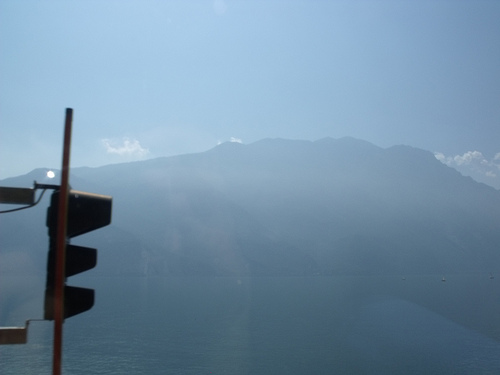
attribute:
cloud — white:
[85, 121, 264, 167]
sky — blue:
[1, 2, 496, 213]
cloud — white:
[422, 139, 497, 200]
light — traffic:
[37, 170, 104, 329]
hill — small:
[210, 136, 247, 156]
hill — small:
[255, 134, 292, 147]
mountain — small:
[1, 131, 498, 260]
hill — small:
[316, 133, 336, 147]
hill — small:
[353, 134, 378, 151]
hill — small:
[394, 139, 411, 154]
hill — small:
[413, 143, 434, 161]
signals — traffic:
[43, 164, 107, 319]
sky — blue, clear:
[0, 3, 496, 186]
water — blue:
[28, 274, 498, 372]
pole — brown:
[48, 105, 77, 373]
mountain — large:
[2, 141, 487, 374]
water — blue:
[10, 293, 494, 373]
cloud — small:
[81, 134, 161, 165]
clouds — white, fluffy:
[431, 145, 496, 199]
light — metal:
[42, 175, 117, 329]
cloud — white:
[92, 129, 149, 179]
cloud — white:
[97, 131, 160, 170]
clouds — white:
[1, 134, 492, 197]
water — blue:
[88, 289, 496, 374]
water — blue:
[157, 357, 189, 368]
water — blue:
[111, 364, 121, 370]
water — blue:
[177, 352, 208, 372]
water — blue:
[149, 340, 194, 370]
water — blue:
[136, 352, 164, 370]